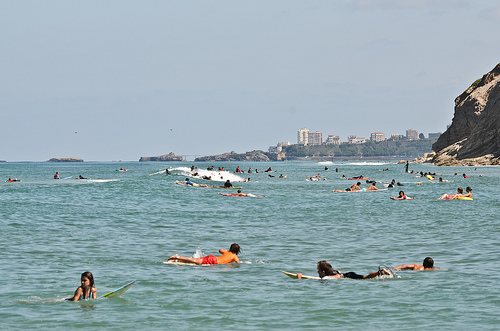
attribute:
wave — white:
[315, 159, 335, 166]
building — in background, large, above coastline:
[296, 125, 311, 145]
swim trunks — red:
[196, 253, 221, 268]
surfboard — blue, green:
[96, 279, 141, 307]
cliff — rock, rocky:
[394, 54, 500, 170]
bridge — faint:
[177, 152, 205, 164]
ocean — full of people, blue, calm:
[0, 159, 497, 330]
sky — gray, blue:
[0, 1, 499, 161]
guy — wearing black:
[294, 256, 403, 283]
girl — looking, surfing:
[63, 270, 99, 301]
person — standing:
[401, 160, 411, 173]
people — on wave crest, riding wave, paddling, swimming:
[161, 162, 233, 182]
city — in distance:
[267, 122, 452, 152]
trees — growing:
[282, 139, 434, 161]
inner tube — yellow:
[455, 195, 475, 202]